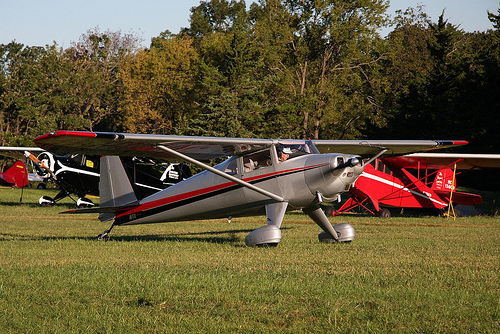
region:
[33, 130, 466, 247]
gray airplane on the ground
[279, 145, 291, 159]
pilot inside gray airplane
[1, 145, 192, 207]
black airplane in the back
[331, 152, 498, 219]
red airplane in the back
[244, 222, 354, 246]
front wheels of a gray airplane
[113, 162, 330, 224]
red and black lines on a gray airplane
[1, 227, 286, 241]
shadow of the gray airplane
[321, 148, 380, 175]
engine of an airplane turned on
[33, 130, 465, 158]
gray wings of an airplane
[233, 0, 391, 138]
big tree behind the airplanes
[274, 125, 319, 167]
A pilot wearing a white cap.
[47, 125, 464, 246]
Black, white and red airplane.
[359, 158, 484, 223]
Red and white airplane.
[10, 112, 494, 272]
Three airplanes on the grass.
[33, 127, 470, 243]
Airplane ready for take off.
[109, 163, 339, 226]
Black and red stripes on the airplane.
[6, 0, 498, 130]
Trees surrounding the air field.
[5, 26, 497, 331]
Private air field.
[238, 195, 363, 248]
Small airplane landing gear.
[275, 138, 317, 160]
A female pilot ready to take off.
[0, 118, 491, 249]
Planes on the grass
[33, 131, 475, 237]
the plane is silver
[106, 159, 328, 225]
black and red stripe on plane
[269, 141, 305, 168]
Person is inside the silver plane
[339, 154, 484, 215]
The plane is red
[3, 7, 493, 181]
Trees behind the planes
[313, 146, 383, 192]
The propeller is spinning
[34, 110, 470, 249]
The pilot is starting the plane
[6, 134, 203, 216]
Black and white plane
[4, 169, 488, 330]
the grass is short, brown, and green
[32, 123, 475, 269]
a silver, red, and black airplane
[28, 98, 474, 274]
a single engine airplane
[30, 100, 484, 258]
a fixed wing aircraft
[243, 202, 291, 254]
the landing gear of an airplane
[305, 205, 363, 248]
the landing gear of an airplane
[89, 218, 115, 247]
the landing gear of an airplane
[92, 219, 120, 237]
the tail wheel of an airplane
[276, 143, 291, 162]
the pilot of an airplane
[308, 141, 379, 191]
the prop of an airplane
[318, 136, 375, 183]
the propeller of an airplane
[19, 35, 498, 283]
parked planes on the grass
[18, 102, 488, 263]
these planes are different colors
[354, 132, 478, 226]
this plane is red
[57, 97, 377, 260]
this plane is silver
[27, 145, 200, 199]
this plane is black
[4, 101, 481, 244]
there are four planes in the shot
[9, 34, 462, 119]
trees near the planes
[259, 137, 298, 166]
a pilot in the plane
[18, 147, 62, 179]
an orange propeller on the black plane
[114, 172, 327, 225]
black and red stripes on the silver plane